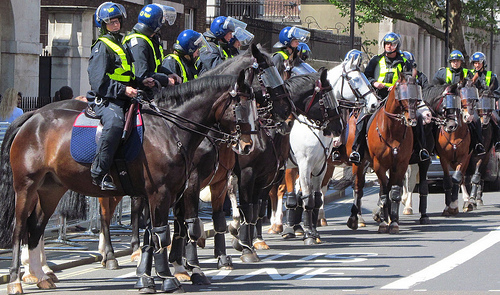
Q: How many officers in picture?
A: Eleven.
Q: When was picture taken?
A: During daylight.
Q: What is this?
A: A police horse patrol unit.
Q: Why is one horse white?
A: It is the lead horse.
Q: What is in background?
A: Buildings.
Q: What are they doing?
A: Gathering to ride.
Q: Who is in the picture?
A: Police officers.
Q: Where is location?
A: A city street.